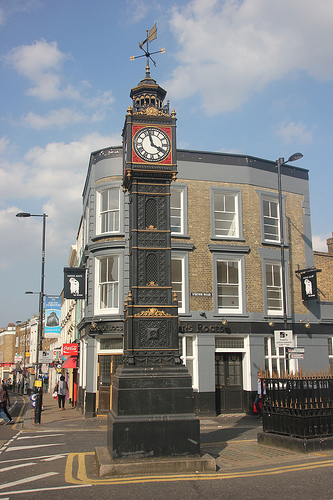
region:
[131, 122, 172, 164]
a red white and black clock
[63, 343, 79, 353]
the coca cola logo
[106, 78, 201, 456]
a tall metal pillar with a clock on it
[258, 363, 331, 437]
gate with metal pointed tips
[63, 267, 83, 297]
a black and white sign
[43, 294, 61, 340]
a blue white and black sign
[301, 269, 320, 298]
a black and white sign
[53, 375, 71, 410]
person walking on sidewalk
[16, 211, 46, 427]
a tall black lightpost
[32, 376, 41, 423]
a black metal post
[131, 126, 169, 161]
a clock on a tower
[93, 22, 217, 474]
a clock tower monument between the streets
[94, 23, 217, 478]
a black and gold tower clock monument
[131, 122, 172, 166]
a red, white and black clock on a tower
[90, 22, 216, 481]
a monumental clock tower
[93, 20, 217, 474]
a clock tower in the middle of the streets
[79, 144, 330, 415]
a three story brown bricked and blue building behind the clock-tower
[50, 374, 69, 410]
a woman walking down the sidewalk beside the building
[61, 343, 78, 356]
a red Coca Cola sign on the building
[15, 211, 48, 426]
street lights on the side of the buildings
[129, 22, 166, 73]
A weathervane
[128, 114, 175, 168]
A clock showing the time 3:58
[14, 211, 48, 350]
A black street lamp pole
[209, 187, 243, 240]
A multipane building window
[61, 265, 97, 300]
A black display flag extending from the side of a building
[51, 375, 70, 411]
A woman wearing black pants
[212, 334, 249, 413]
An entryway door into a building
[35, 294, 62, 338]
A decorative flag extending from a flag pole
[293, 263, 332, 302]
A decorative black flag extending from the side of a building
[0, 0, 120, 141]
Cloudy blue sky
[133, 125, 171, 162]
The clock face is white.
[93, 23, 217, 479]
A clock on a pedestal.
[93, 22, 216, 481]
The clock pedestal is black.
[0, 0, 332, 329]
The sky is blue.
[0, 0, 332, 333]
The sky has a few clouds in it.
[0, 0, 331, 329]
The clouds are white.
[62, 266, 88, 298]
A banner.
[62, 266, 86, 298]
The banner is black.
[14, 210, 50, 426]
A street light.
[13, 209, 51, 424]
The steet light is made of metal.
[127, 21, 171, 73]
The steeple is at the top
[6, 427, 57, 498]
The ground has white paint on it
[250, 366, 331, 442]
The fence is black with gold tip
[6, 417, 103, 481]
The ground is covered in shadow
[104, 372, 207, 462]
The base has some staining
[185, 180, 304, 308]
Windows on side of the building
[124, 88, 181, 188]
The tower has a clock on it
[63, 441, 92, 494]
Yellow paint on the pavement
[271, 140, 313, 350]
Light by the side of the road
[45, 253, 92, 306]
Flag on side of building